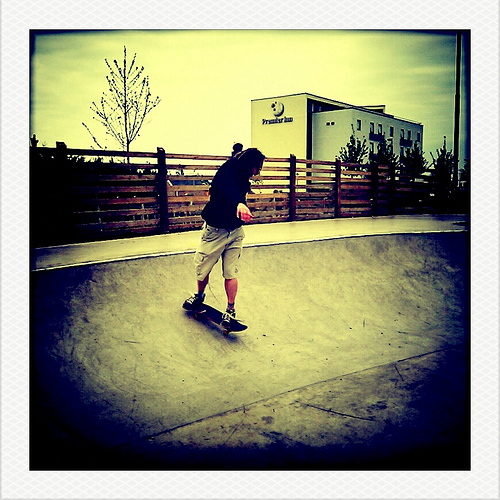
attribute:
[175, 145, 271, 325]
man — skateboarding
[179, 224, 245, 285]
shorts — tan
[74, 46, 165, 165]
tree — with no leaves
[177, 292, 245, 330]
sneakers — black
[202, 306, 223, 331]
skateboard — black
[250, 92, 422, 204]
building — with windows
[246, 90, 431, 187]
building — with words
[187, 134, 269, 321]
man — skateboarding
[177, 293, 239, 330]
shoes — black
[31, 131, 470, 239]
fence — wooden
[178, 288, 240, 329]
shoes — black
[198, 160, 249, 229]
jacket — black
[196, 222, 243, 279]
shorts — tan, cargo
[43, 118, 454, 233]
fence — wood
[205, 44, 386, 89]
sky — overcast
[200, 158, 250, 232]
hoodie — black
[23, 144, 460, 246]
fence — brown